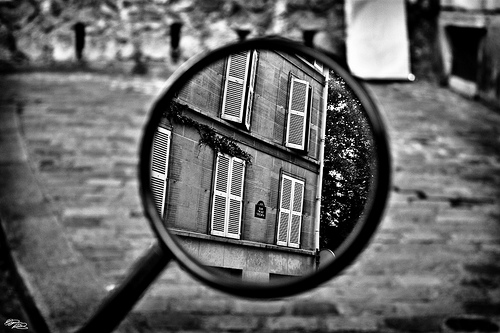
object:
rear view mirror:
[138, 37, 392, 300]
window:
[210, 152, 246, 238]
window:
[283, 77, 322, 160]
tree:
[323, 70, 376, 250]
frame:
[137, 37, 390, 302]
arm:
[70, 245, 171, 333]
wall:
[158, 48, 330, 281]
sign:
[254, 200, 266, 219]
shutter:
[210, 151, 232, 237]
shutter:
[285, 78, 310, 150]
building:
[148, 46, 330, 284]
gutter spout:
[315, 64, 329, 251]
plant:
[165, 107, 253, 166]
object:
[343, 1, 417, 81]